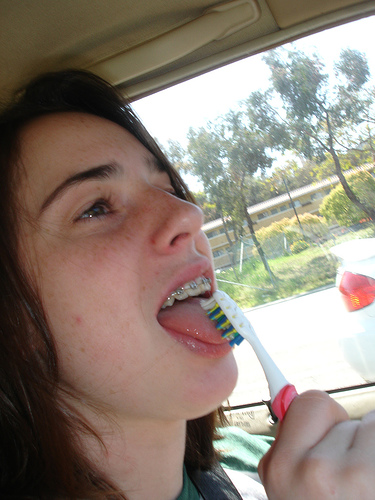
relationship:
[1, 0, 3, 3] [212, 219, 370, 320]
zebra in grass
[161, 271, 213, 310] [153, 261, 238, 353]
teeth are in girls mouth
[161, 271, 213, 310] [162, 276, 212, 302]
teeth have braces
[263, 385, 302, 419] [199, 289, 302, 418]
grip of toothbrush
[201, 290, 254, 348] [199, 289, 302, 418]
head of toothbrush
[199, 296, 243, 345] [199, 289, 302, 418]
bristles of a toothbrush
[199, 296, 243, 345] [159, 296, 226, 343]
bristles on girls tongue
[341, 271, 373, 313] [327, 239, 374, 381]
tail light of a car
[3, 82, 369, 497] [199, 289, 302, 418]
girl holding toothbrush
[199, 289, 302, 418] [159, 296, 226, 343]
toothbrush on girls tongue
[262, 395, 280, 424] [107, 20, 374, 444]
lock on a car door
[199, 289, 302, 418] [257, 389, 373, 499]
toothbrush in girls hand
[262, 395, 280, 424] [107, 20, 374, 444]
lock on car door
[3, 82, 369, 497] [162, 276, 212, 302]
girl has braces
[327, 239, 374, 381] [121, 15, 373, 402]
car outside of window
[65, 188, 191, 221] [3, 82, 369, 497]
eyes of girl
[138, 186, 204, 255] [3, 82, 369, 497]
nose of girl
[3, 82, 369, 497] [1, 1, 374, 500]
girl sitting in her car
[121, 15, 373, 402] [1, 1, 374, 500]
window in car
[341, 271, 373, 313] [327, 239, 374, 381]
tail light on car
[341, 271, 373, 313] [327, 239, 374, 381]
tail light of car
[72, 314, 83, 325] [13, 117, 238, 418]
pimple on girls face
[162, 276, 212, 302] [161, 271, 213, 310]
braces on her teeth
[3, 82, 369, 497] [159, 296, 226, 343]
girl brushing her tongue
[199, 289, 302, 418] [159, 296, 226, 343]
toothbrush on her tongue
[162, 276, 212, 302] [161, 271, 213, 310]
braces on girls teeth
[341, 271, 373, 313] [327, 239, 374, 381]
tail light on white car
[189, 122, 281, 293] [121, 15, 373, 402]
tree beyond window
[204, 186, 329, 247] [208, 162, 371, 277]
windows of building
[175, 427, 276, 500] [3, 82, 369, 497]
shirt of girl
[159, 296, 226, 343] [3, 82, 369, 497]
tongue of girl